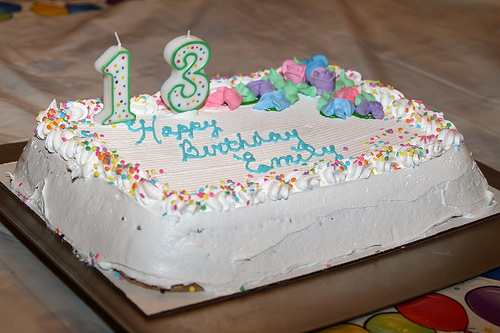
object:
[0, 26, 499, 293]
cake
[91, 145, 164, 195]
sprinkles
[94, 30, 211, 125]
13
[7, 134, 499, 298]
frosting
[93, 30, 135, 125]
1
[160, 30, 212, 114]
3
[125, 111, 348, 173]
words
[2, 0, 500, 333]
table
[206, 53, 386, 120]
roses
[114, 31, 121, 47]
wicker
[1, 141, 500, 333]
cake pan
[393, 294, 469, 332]
balloon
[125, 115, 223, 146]
happy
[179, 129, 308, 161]
birthday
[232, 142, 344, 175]
emily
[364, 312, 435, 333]
balloon